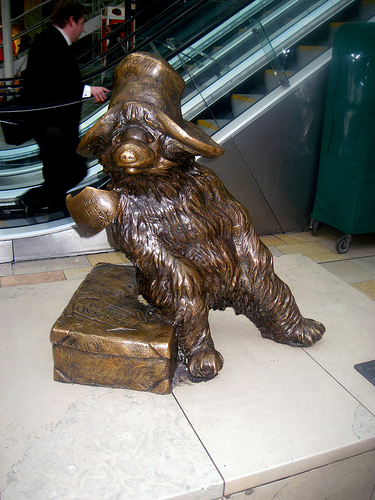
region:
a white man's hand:
[49, 45, 109, 106]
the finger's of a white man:
[90, 90, 112, 99]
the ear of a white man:
[63, 11, 71, 26]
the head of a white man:
[54, 2, 93, 41]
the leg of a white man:
[19, 143, 74, 214]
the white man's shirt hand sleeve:
[83, 80, 89, 98]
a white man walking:
[11, 0, 101, 200]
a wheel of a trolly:
[332, 230, 355, 255]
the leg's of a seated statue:
[170, 293, 353, 378]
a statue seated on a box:
[91, 40, 337, 384]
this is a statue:
[99, 58, 296, 332]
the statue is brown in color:
[143, 188, 193, 246]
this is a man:
[40, 2, 85, 146]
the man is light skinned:
[91, 81, 104, 99]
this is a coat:
[42, 47, 68, 89]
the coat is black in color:
[37, 55, 62, 86]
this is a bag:
[4, 91, 31, 132]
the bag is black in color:
[13, 96, 29, 129]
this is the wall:
[265, 96, 301, 178]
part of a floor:
[227, 414, 257, 481]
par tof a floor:
[241, 395, 261, 443]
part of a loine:
[184, 404, 230, 441]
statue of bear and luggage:
[40, 47, 336, 423]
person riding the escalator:
[10, 15, 115, 228]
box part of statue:
[45, 249, 190, 384]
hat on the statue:
[72, 50, 224, 153]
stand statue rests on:
[13, 263, 374, 472]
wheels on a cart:
[301, 218, 354, 249]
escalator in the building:
[8, 8, 314, 234]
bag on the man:
[4, 101, 47, 146]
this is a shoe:
[15, 195, 44, 225]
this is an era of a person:
[67, 15, 77, 32]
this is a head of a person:
[43, 5, 97, 42]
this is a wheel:
[327, 235, 355, 250]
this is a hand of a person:
[83, 82, 109, 106]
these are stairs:
[3, 1, 319, 159]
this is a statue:
[60, 44, 331, 389]